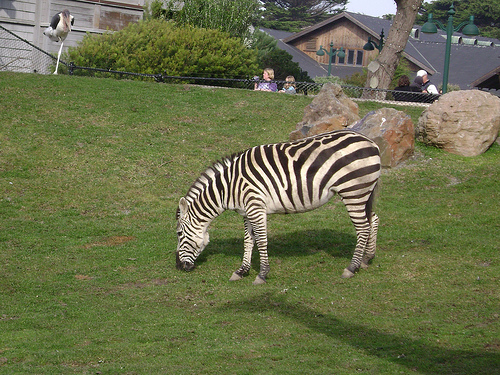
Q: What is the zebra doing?
A: Grazing.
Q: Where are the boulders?
A: The grass.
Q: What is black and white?
A: Zebra.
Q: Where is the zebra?
A: At zoo.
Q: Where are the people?
A: At zoo.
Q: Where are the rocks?
A: Behind zebra.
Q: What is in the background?
A: Fence.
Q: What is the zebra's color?
A: Gray and white.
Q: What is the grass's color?
A: Green.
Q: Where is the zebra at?
A: An enclosed field.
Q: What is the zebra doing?
A: Grazing.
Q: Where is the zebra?
A: The Zoo.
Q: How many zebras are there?
A: One.